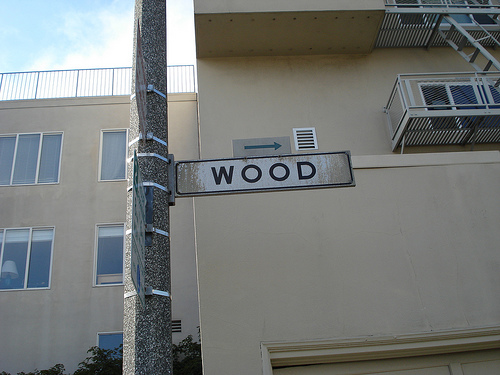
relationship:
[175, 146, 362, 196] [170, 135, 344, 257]
sign in english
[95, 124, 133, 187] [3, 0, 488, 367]
window of building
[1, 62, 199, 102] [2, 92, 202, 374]
metal bars on building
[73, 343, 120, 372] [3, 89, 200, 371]
plant near wall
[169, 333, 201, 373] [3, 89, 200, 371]
plant near wall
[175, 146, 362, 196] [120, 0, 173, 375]
sign on mast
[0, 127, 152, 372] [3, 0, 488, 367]
windows on building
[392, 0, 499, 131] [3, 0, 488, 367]
windows on building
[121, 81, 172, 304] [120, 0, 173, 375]
rungs on mast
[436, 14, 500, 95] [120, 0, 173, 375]
ladder on mast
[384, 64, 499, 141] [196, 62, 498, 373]
railing on building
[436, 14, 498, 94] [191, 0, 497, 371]
ladder on building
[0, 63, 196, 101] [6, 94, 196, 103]
metal bars on roof